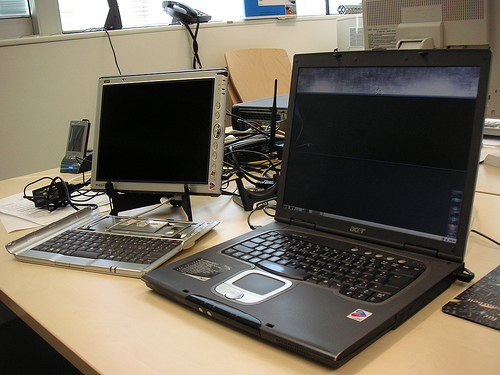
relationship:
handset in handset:
[163, 0, 199, 20] [161, 0, 211, 23]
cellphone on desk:
[64, 120, 91, 161] [0, 124, 498, 375]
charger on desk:
[58, 151, 92, 173] [0, 124, 498, 375]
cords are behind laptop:
[22, 111, 286, 212] [141, 49, 493, 370]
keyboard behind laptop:
[483, 118, 499, 139] [141, 49, 493, 370]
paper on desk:
[1, 184, 114, 234] [0, 124, 498, 375]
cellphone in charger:
[64, 120, 91, 161] [58, 151, 92, 173]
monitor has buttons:
[89, 68, 228, 197] [209, 103, 223, 182]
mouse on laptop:
[231, 271, 285, 296] [141, 49, 493, 370]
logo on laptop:
[345, 308, 374, 323] [141, 49, 493, 370]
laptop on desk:
[141, 49, 493, 370] [0, 124, 498, 375]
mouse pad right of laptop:
[441, 265, 500, 331] [141, 49, 493, 370]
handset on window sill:
[161, 0, 211, 23] [1, 12, 362, 49]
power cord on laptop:
[453, 268, 473, 282] [141, 49, 493, 370]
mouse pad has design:
[441, 265, 500, 331] [441, 263, 500, 330]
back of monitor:
[360, 1, 499, 116] [362, 1, 499, 120]